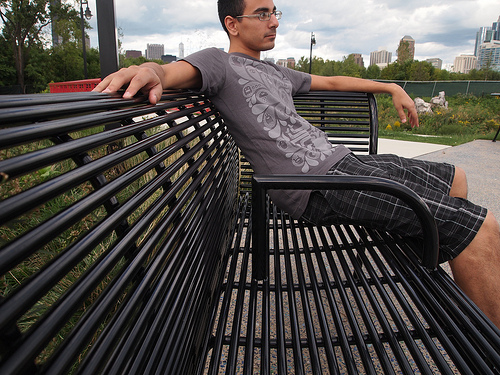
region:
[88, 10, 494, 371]
A man is sitting on a bench.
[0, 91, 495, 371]
A bench is made of metal pipes.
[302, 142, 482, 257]
A man is wearing shorts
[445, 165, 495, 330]
The knees are bent.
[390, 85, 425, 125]
The fingers of the hand are pointing down.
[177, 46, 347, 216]
The tee shirt is gray and white.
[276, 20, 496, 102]
City buildings are behind a fence and treeline.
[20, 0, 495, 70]
The sky is mostly cloudy.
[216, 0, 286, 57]
A face is wearing glasses.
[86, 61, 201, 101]
An arm is resting on a surface of pipe.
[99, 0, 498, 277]
man sitting on a bench.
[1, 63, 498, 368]
the fence is black.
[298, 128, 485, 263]
man is wearing shorts.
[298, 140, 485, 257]
the shorts are plaid.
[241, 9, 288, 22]
glasses on the man's face.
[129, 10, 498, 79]
buildings in the background.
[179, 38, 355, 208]
the man's shirt is grey.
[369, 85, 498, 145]
the grass is green.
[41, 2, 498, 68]
the sky is cloudy.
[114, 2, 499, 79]
the sky is blue.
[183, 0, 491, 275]
man sitting on a bench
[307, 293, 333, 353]
wire bottom on bench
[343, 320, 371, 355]
wire bottom on bench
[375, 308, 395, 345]
wire bottom on bench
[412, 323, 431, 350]
wire bottom on bench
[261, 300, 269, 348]
wire bottom on bench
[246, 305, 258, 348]
wire bottom on bench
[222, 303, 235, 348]
wire bottom on bench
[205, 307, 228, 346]
wire bottom on bench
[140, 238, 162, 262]
wire bottom on bench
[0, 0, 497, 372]
a man sitting on a metal bench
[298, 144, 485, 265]
black shorts with stripes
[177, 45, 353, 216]
a grey t shirt with a design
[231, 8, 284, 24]
man has eye glasses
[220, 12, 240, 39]
the man's ear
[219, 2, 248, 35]
black hair cut short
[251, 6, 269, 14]
man's black eyebrow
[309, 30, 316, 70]
a light on a post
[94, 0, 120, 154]
a metal pole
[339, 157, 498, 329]
the man's leg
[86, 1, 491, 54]
gray clouds in sky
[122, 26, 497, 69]
city skyline on horizon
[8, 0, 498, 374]
man sitting on bench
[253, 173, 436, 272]
curved pole on bench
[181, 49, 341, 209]
short sleeved tee shirt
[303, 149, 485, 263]
plaid shorts on man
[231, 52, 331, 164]
design on front of shirt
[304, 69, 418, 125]
arm resting on bench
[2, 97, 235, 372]
back of black metal bench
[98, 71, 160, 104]
fingers on top of bench